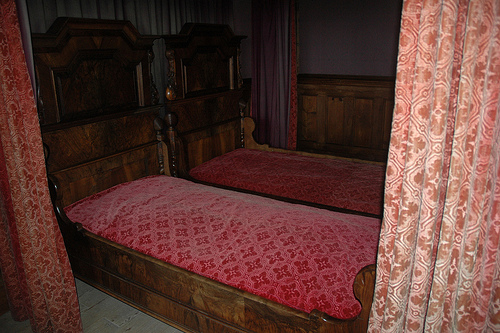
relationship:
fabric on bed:
[78, 174, 376, 314] [43, 134, 388, 331]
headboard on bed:
[29, 16, 175, 207] [12, 14, 383, 331]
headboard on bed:
[164, 18, 266, 175] [162, 21, 386, 213]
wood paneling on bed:
[184, 127, 237, 153] [12, 14, 383, 331]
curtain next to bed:
[366, 0, 498, 332] [58, 148, 377, 322]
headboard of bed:
[33, 17, 170, 212] [12, 14, 383, 331]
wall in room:
[307, 7, 396, 77] [6, 4, 401, 325]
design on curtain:
[400, 149, 460, 239] [378, 122, 478, 229]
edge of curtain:
[45, 194, 79, 254] [0, 5, 99, 330]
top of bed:
[140, 195, 233, 236] [46, 84, 402, 329]